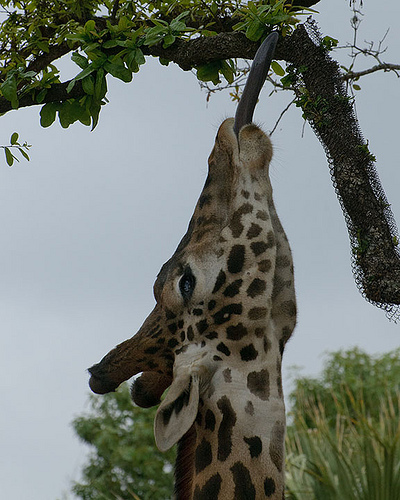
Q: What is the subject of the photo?
A: Animal.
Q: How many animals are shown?
A: One.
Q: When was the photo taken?
A: Daytime.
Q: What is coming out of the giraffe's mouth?
A: Tongue.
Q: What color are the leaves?
A: Green.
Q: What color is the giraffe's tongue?
A: Black.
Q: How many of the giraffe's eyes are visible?
A: One.